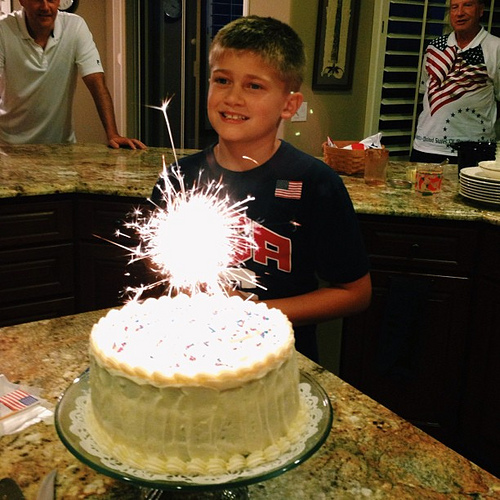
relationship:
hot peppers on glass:
[416, 175, 441, 192] [414, 162, 447, 216]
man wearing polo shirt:
[1, 1, 148, 150] [1, 8, 104, 145]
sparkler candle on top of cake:
[88, 92, 270, 318] [84, 291, 313, 479]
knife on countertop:
[36, 469, 59, 500] [0, 297, 500, 499]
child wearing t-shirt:
[145, 12, 372, 363] [151, 140, 367, 339]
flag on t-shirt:
[274, 177, 303, 200] [151, 140, 367, 339]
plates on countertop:
[459, 164, 500, 204] [1, 140, 500, 226]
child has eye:
[145, 12, 372, 363] [245, 82, 266, 90]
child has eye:
[145, 12, 372, 363] [213, 76, 233, 86]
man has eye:
[404, 1, 500, 167] [463, 3, 474, 8]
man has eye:
[404, 1, 500, 167] [451, 4, 459, 10]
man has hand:
[1, 1, 148, 150] [108, 136, 147, 152]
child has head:
[145, 12, 372, 363] [205, 16, 306, 141]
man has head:
[1, 1, 148, 150] [18, 1, 61, 28]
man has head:
[404, 1, 500, 167] [447, 0, 485, 32]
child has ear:
[145, 12, 372, 363] [280, 93, 304, 121]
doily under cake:
[69, 382, 322, 487] [84, 291, 313, 479]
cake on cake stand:
[84, 291, 313, 479] [54, 366, 334, 500]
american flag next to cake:
[1, 388, 41, 422] [84, 291, 313, 479]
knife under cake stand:
[36, 469, 59, 500] [54, 366, 334, 500]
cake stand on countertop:
[54, 366, 334, 500] [0, 297, 500, 499]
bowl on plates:
[479, 159, 500, 178] [459, 164, 500, 204]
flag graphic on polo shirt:
[424, 33, 490, 116] [411, 25, 499, 157]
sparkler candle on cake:
[88, 92, 270, 318] [84, 291, 313, 479]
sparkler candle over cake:
[88, 92, 270, 318] [84, 291, 313, 479]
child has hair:
[145, 12, 372, 363] [207, 15, 309, 95]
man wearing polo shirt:
[404, 1, 500, 167] [411, 25, 499, 157]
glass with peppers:
[414, 162, 447, 216] [416, 175, 441, 192]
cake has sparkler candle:
[84, 291, 313, 479] [88, 92, 270, 318]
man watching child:
[1, 1, 148, 150] [145, 12, 372, 363]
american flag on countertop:
[1, 388, 41, 422] [0, 297, 500, 499]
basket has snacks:
[321, 140, 384, 178] [326, 132, 383, 150]